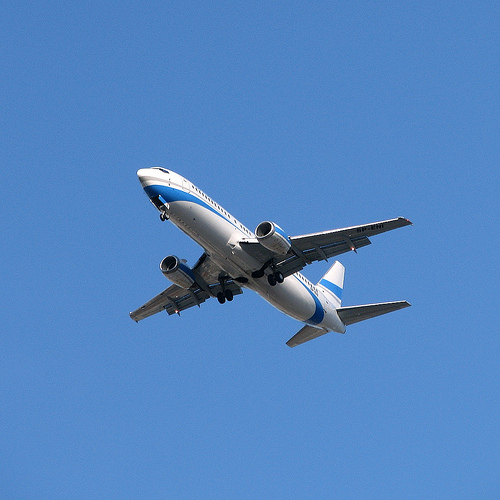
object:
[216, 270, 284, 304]
wheels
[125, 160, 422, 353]
people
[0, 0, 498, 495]
clear sky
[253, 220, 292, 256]
turbine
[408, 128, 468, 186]
ground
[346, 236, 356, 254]
light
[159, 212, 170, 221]
wheels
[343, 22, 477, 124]
brown trunk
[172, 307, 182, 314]
light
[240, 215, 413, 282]
wing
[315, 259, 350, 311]
tail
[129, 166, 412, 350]
airplane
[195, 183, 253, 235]
passenger windows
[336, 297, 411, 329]
wing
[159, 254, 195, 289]
turbines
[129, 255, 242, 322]
wing